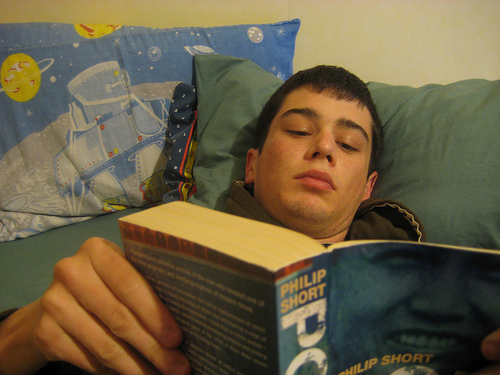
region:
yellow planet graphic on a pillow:
[0, 51, 57, 103]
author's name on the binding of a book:
[278, 267, 327, 313]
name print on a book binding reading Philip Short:
[276, 267, 327, 313]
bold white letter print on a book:
[278, 296, 334, 348]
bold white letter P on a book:
[279, 296, 336, 349]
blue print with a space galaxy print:
[1, 17, 303, 243]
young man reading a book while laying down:
[2, 60, 497, 372]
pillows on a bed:
[1, 16, 498, 247]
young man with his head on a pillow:
[187, 50, 498, 241]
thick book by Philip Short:
[114, 195, 496, 373]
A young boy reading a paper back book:
[40, 55, 493, 370]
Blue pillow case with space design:
[1, 22, 299, 239]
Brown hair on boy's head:
[258, 63, 388, 150]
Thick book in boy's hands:
[126, 200, 498, 371]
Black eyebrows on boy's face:
[281, 104, 368, 132]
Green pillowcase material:
[195, 50, 260, 207]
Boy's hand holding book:
[27, 240, 191, 372]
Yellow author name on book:
[277, 270, 332, 303]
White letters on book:
[282, 300, 337, 372]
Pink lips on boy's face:
[295, 166, 341, 191]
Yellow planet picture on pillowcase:
[6, 53, 54, 100]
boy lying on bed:
[0, 63, 429, 363]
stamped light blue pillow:
[0, 18, 297, 245]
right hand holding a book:
[0, 220, 174, 372]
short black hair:
[245, 63, 382, 159]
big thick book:
[117, 195, 493, 371]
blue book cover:
[115, 214, 497, 366]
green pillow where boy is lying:
[198, 48, 498, 257]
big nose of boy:
[306, 128, 336, 160]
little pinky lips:
[290, 168, 342, 191]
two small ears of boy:
[236, 142, 381, 207]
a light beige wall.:
[340, 5, 463, 55]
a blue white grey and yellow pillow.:
[4, 71, 144, 149]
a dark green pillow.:
[415, 138, 470, 197]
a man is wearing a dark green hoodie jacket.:
[364, 208, 419, 236]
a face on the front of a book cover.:
[326, 237, 498, 374]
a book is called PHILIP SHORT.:
[268, 257, 336, 373]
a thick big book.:
[111, 195, 499, 373]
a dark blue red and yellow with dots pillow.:
[161, 80, 199, 197]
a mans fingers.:
[0, 232, 194, 373]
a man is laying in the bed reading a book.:
[0, 0, 499, 373]